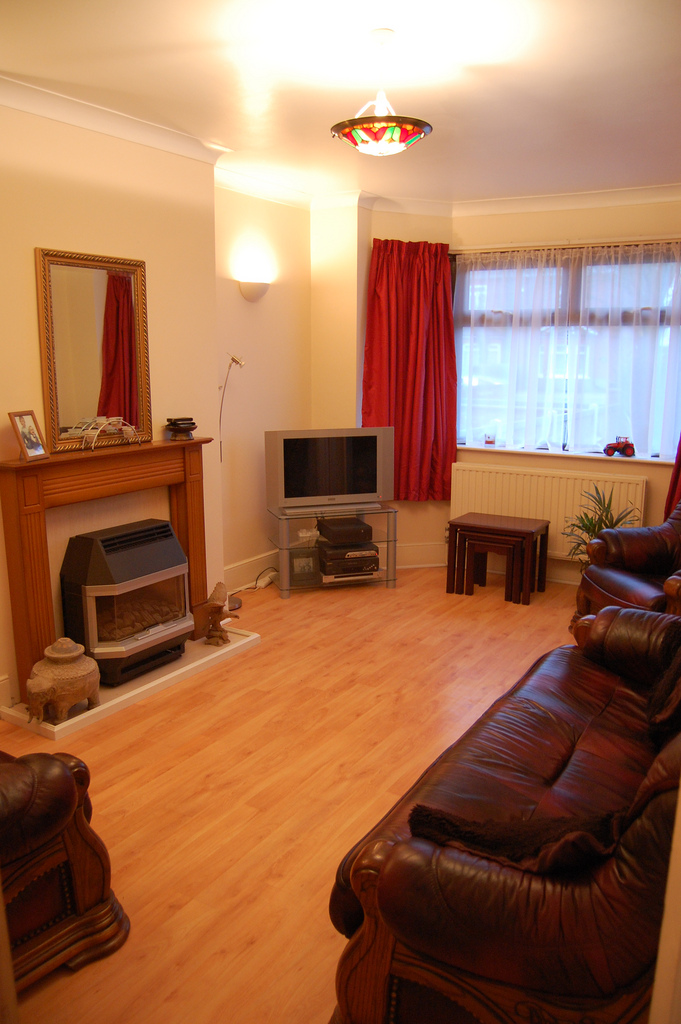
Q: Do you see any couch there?
A: Yes, there is a couch.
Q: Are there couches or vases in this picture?
A: Yes, there is a couch.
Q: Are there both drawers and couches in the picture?
A: No, there is a couch but no drawers.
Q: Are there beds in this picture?
A: No, there are no beds.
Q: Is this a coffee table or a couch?
A: This is a couch.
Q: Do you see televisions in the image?
A: Yes, there is a television.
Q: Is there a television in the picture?
A: Yes, there is a television.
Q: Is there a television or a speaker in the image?
A: Yes, there is a television.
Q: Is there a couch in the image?
A: Yes, there is a couch.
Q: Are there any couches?
A: Yes, there is a couch.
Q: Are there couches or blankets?
A: Yes, there is a couch.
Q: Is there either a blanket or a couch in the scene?
A: Yes, there is a couch.